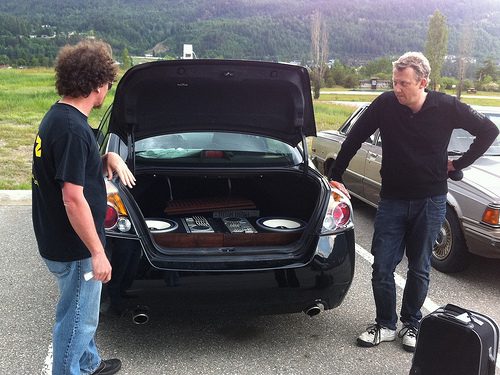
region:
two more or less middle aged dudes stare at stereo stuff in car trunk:
[15, 21, 499, 373]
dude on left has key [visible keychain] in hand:
[80, 267, 95, 283]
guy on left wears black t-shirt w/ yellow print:
[27, 102, 108, 267]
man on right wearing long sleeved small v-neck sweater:
[313, 83, 498, 195]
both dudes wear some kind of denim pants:
[35, 185, 452, 371]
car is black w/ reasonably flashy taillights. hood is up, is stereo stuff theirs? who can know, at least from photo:
[87, 47, 360, 332]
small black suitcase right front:
[392, 300, 497, 373]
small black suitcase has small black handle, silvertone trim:
[392, 295, 497, 371]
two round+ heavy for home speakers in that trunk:
[135, 205, 315, 240]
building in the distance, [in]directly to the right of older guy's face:
[353, 76, 395, 92]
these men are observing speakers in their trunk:
[16, 2, 498, 307]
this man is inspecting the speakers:
[34, 26, 167, 373]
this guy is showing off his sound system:
[301, 55, 498, 308]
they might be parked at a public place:
[46, 45, 498, 327]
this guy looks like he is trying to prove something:
[328, 34, 498, 339]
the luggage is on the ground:
[395, 279, 498, 374]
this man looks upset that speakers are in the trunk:
[128, 56, 499, 368]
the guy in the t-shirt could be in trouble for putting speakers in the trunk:
[35, 22, 437, 374]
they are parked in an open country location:
[8, 3, 495, 222]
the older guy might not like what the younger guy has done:
[41, 16, 433, 353]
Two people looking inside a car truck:
[21, 30, 492, 356]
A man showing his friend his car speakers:
[20, 36, 490, 361]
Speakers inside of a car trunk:
[130, 161, 327, 247]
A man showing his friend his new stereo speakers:
[27, 32, 497, 367]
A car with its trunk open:
[127, 55, 322, 280]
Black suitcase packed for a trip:
[417, 301, 495, 372]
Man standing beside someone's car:
[320, 45, 498, 301]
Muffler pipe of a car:
[125, 302, 155, 327]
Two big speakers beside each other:
[150, 210, 297, 237]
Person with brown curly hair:
[45, 38, 118, 114]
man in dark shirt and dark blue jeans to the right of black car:
[330, 50, 498, 347]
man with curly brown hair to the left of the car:
[30, 40, 135, 370]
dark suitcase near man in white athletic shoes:
[405, 300, 495, 370]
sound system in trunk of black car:
[145, 212, 300, 232]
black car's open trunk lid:
[110, 55, 315, 141]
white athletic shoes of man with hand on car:
[356, 320, 411, 350]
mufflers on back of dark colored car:
[130, 302, 325, 327]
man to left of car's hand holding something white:
[80, 250, 111, 285]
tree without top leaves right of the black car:
[308, 11, 328, 100]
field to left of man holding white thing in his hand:
[3, 66, 32, 187]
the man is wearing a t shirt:
[23, 102, 110, 258]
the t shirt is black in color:
[32, 101, 108, 259]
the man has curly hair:
[53, 42, 119, 102]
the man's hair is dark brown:
[54, 39, 117, 99]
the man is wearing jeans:
[38, 248, 103, 372]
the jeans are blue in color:
[41, 253, 111, 372]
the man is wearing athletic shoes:
[359, 321, 421, 353]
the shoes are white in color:
[361, 320, 423, 351]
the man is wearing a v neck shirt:
[331, 93, 496, 186]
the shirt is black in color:
[332, 89, 497, 198]